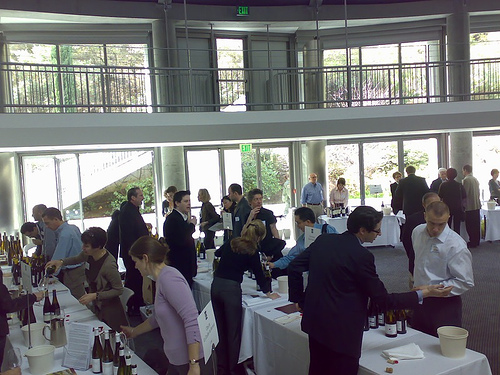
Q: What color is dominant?
A: White.